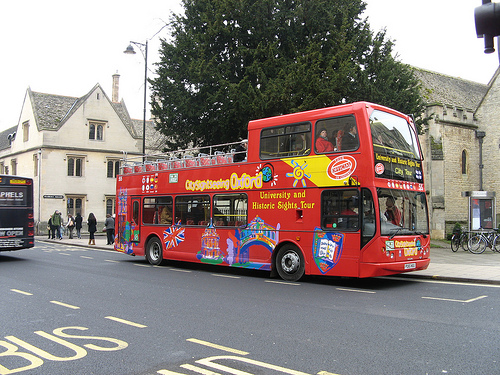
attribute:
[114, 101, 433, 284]
bus — double-decker, red, double decker, tall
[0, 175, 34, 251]
bus — black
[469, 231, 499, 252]
bicycle — park, parked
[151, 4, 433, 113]
tree — green, large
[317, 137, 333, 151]
jacket — red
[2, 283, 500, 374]
street — paved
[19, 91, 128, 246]
building — white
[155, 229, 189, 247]
flag — british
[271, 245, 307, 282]
wheel — black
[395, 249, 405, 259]
headlight — off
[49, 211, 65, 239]
person — walking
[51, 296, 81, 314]
line — white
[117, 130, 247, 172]
top — open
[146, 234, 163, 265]
tire — rubber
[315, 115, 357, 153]
pane — window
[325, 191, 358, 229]
window — tinted